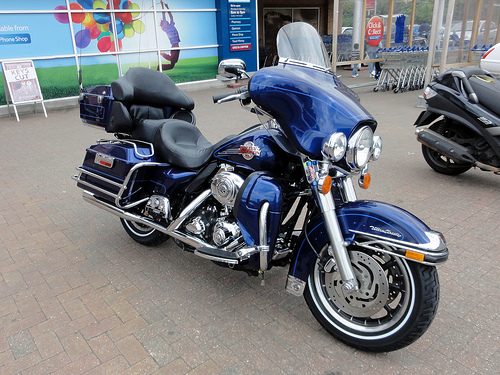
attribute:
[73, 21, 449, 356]
motorcycle — blue, shiny, parked, leaning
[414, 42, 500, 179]
motorcycle — black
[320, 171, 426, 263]
reflectors — orange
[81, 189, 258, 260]
tailpipe — silver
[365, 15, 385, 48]
sticker — red, white, round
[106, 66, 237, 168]
seat — black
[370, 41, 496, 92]
carts — row, metal, together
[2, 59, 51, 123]
sign — small, white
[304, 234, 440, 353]
tire — part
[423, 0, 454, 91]
pole — tall, metal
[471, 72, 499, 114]
seat — black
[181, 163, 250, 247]
engine — silver, part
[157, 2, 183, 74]
woman — jumping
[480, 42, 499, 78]
car — white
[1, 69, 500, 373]
road — part